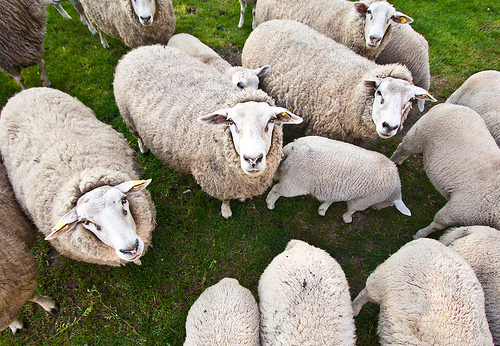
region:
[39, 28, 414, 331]
sheep in a field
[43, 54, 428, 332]
sheep standing in a field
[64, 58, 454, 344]
sheep in an area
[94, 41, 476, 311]
sheep standing in an area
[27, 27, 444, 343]
sheep on the grass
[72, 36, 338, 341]
sheep standign on grass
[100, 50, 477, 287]
sheep standing on green grass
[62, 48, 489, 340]
a field of grass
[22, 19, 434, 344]
a field of green grass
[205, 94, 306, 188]
head of a sheep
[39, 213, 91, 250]
ear of a sheep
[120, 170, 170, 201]
ear of a sheep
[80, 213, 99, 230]
eye of a sheep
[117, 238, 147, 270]
nose of a sheep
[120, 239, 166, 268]
mouth of a sheep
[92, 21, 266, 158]
body of a sheep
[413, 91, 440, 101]
ear of a sheep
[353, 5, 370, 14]
ear of a sheep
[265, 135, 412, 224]
a lamb inside a group of sheep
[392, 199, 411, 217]
the white ear of a lamb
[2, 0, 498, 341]
green grass under a group of sheep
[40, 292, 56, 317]
the hoof of a sheep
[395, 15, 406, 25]
a yellow tag in a sheep's ear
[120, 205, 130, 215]
a black spot under a sheep's eye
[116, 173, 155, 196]
the ear of a sheep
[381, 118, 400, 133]
the black nose of a sheep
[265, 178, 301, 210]
the hind leg of a lamb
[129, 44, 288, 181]
big sheep next to little sheep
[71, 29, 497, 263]
many sheep in a pasture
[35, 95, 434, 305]
sheep standing on green grass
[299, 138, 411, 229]
baby sheep eating grass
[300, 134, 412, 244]
little sheep eating green grass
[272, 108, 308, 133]
yellow tag on a sheep ear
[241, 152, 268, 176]
big nose on a white sheep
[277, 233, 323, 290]
tail on a white sheep butt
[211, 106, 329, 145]
eyes and ears on a sheep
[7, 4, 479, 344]
sheep in the grass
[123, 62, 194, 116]
wool of a sheep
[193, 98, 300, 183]
head of a sheep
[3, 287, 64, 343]
front hooves of a sheep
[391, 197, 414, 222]
right ear of a lamb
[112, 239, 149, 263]
nose and mouth of a sheep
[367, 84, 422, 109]
eyes of a sheep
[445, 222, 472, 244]
tail of a sheep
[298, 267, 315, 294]
dirt on sheep's wool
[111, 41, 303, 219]
sheep has yellow tag on its ear